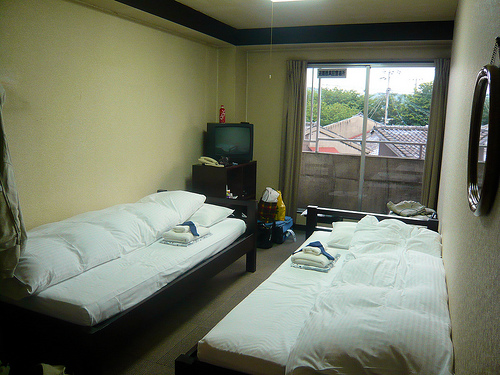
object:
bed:
[2, 188, 257, 375]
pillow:
[328, 219, 355, 249]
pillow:
[187, 199, 236, 228]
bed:
[174, 204, 455, 375]